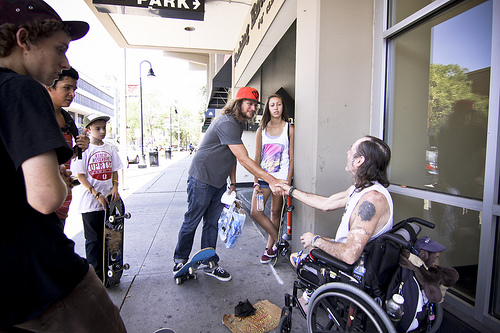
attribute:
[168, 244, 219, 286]
skateboard — tilted 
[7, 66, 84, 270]
t-shirt — black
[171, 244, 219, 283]
blue skateboard — blue 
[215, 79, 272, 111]
hat — red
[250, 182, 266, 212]
bottle — plastic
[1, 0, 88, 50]
hat — black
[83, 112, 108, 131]
hat — black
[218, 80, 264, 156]
man — smiling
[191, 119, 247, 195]
shirt — grey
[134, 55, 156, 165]
light — grey